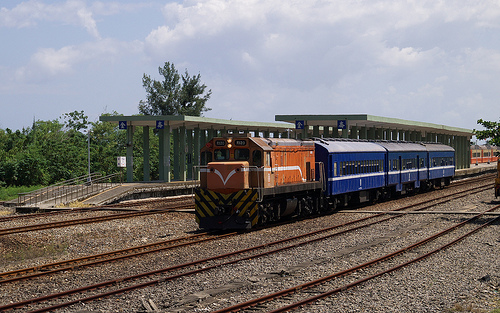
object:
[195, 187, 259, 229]
stripes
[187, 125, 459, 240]
train engine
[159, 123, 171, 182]
support post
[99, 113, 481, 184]
covered platform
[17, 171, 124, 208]
railing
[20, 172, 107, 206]
ramp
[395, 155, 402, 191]
door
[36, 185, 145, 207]
ramp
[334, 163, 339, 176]
window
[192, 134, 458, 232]
passenger car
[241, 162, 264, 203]
railing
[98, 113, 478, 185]
train platform